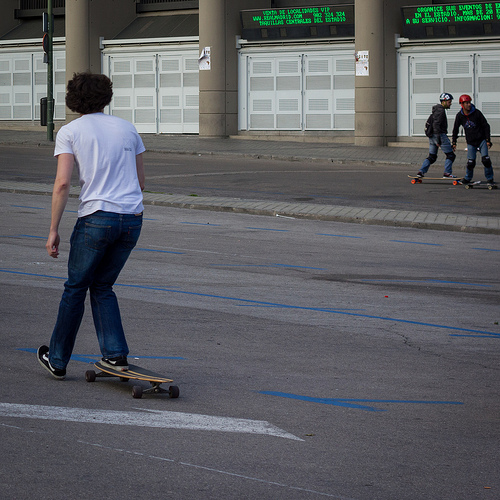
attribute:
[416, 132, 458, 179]
jeans — blue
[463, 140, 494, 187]
jeans — blue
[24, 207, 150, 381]
jeans — blue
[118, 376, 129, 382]
wheel — black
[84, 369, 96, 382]
wheel — black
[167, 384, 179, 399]
wheel — black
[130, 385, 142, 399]
wheel — black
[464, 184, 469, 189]
wheel — black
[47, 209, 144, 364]
jeans — blue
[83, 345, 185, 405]
skateboard — black, tan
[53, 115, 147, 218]
white shirt — white 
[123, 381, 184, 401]
wheels — black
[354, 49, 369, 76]
flyer — white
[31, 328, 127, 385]
shoes — white, black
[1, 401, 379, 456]
arrow/street — white 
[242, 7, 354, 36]
board — electronic, announcement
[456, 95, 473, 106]
helmet — red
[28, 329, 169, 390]
shoes — black, white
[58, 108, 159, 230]
tee shirt — white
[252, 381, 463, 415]
lines — blue 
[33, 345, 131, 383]
shoes — black, white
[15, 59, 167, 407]
he — skateboarding